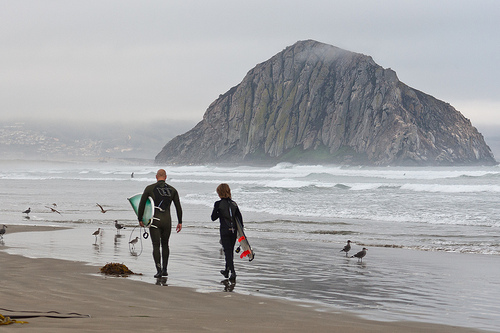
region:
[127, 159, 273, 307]
two people walking down the beach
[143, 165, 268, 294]
two people wearing black wetsuits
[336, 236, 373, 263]
two birds standing on the beach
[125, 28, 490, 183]
large rock sticking out of the water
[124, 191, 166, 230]
surfboard under the arm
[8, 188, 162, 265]
several bireds on the beach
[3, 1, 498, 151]
thick fog in the sky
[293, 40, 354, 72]
fog over the top of the rock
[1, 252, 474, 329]
sand along the shoreline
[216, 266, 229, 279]
foot lifted off the ground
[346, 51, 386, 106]
edge of a hill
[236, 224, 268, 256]
part of a board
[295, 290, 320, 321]
edge of a shore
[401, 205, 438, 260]
part of a water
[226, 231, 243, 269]
part of a trouser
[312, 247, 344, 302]
part of a beach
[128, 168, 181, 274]
the man is carrying a surfboard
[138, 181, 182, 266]
the man is wearing a wetsuit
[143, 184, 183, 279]
the wetsuit is black in color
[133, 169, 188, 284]
the man is walking on the shore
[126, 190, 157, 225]
the surfboard is green in color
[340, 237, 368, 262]
two birds are on the shore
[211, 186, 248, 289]
a woman is walking on the shore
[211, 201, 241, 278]
the woman is wearing a wetsuit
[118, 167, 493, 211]
the waves are reaching the shore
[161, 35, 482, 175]
a mountain is in the distance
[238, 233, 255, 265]
part of a board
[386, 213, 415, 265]
edge of a shore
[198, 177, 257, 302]
a woman clutching a surfboard.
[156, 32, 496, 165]
a giant mountain on a beach.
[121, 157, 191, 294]
a man clutching a short board.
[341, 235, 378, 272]
a small bird on a beach.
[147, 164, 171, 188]
a man with a bald head.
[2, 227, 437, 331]
a section of a sandy beach.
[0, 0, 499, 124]
a cloud filled beach sky.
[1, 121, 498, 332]
a large body water.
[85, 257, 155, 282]
sea weed on a beach.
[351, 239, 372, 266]
a lone seagull.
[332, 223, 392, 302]
birds in water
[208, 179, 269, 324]
boy walking on beach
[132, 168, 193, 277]
a man on beach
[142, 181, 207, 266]
the suit is black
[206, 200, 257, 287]
the suit is black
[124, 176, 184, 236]
man carrying a board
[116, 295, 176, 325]
the sand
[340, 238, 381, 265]
two birds in the water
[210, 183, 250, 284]
a person walking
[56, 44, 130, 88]
the sky is cloudy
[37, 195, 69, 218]
a bird flying